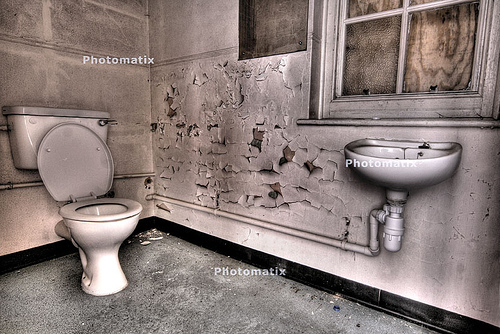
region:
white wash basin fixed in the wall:
[320, 134, 463, 201]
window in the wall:
[326, 12, 491, 122]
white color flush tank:
[8, 95, 117, 160]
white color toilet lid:
[31, 125, 123, 195]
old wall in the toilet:
[184, 115, 339, 248]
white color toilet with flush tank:
[6, 94, 158, 299]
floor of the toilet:
[143, 266, 267, 317]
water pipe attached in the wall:
[182, 197, 403, 252]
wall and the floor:
[171, 222, 401, 277]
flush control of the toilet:
[96, 119, 118, 125]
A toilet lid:
[46, 115, 112, 200]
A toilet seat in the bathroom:
[62, 182, 157, 297]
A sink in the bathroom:
[332, 99, 474, 218]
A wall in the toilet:
[185, 76, 282, 191]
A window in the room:
[342, 2, 472, 94]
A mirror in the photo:
[250, 17, 300, 64]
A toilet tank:
[12, 106, 128, 139]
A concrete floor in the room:
[154, 253, 224, 312]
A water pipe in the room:
[246, 204, 346, 244]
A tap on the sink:
[392, 139, 444, 156]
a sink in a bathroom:
[337, 128, 472, 278]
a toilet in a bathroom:
[10, 96, 168, 307]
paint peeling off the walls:
[162, 73, 310, 207]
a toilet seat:
[56, 194, 149, 228]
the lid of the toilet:
[33, 122, 130, 213]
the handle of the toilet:
[96, 112, 121, 134]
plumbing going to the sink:
[168, 179, 437, 267]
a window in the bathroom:
[311, 11, 494, 143]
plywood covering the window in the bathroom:
[416, 23, 466, 80]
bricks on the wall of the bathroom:
[55, 8, 159, 67]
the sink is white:
[327, 116, 464, 268]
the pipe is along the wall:
[131, 165, 392, 268]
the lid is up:
[20, 115, 127, 204]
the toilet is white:
[12, 82, 161, 305]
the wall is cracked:
[143, 35, 328, 222]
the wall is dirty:
[134, 58, 346, 231]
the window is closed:
[304, 0, 494, 140]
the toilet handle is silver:
[85, 104, 130, 139]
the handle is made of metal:
[85, 107, 124, 136]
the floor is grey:
[27, 275, 239, 322]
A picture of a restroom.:
[4, 6, 493, 326]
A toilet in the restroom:
[1, 102, 153, 299]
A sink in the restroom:
[335, 135, 467, 261]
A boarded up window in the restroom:
[295, 3, 492, 128]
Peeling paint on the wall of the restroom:
[146, 61, 352, 240]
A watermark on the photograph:
[76, 49, 160, 71]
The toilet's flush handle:
[98, 115, 118, 130]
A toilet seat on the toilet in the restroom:
[58, 197, 146, 224]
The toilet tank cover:
[0, 100, 113, 124]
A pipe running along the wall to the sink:
[141, 188, 410, 258]